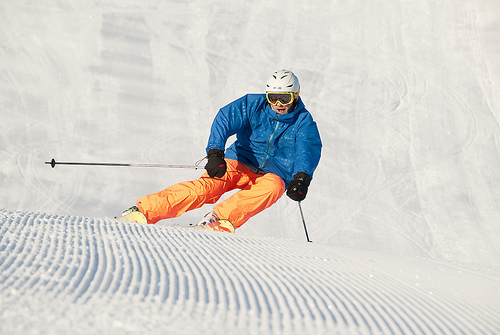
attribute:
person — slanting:
[184, 59, 331, 207]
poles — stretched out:
[40, 153, 199, 174]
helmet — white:
[260, 65, 302, 95]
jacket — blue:
[213, 114, 330, 165]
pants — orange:
[145, 155, 285, 228]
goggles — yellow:
[263, 89, 295, 106]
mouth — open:
[276, 107, 286, 115]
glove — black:
[202, 149, 229, 183]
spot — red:
[218, 162, 227, 170]